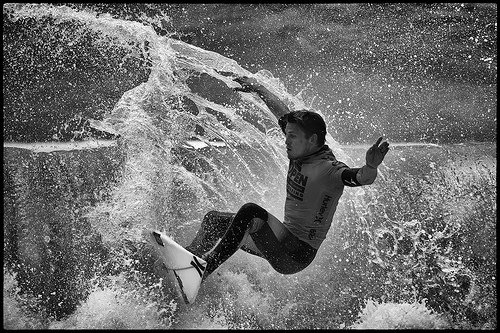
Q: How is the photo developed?
A: In black and white.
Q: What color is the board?
A: White.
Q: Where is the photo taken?
A: In the ocean.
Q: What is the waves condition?
A: Choppy.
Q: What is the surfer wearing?
A: A bodysuit.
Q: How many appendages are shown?
A: 4.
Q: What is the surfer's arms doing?
A: Trying to balance himself.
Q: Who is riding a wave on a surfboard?
A: A man.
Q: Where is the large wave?
A: In the ocean.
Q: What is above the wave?
A: The sky.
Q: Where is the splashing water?
A: Above the wave.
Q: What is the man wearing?
A: A wetsuit.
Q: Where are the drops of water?
A: Above the wave.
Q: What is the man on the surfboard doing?
A: Riding a wave.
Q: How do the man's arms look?
A: Outstretched.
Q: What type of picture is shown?
A: Black and white.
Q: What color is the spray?
A: White.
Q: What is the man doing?
A: Falling.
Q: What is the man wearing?
A: Wetsuit.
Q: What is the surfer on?
A: Surfboard.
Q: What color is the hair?
A: Black.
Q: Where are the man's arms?
A: Raised.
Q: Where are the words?
A: Man's top.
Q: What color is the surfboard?
A: White.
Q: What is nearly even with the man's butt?
A: Feet.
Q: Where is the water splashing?
A: Around the man.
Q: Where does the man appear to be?
A: In an indoor water park.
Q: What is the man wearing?
A: A wetsuit.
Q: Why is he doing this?
A: For entertainment.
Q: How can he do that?
A: With practice.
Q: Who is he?
A: A surfer.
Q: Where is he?
A: In the ocean.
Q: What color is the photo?
A: Black and white.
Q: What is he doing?
A: Surfing.